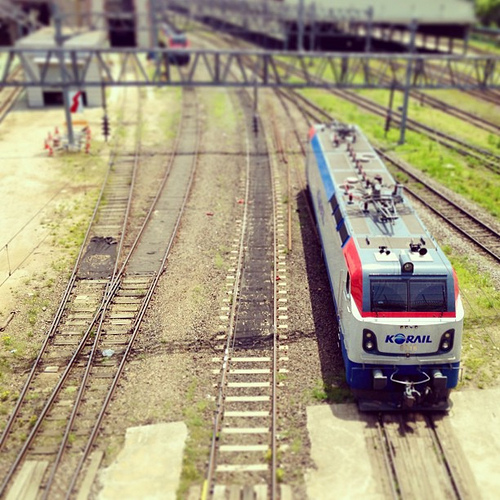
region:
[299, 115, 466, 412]
the train on the railroad tracks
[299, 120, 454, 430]
the model toy train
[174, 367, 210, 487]
the grass on the ground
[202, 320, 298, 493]
the railroad tracks on the ground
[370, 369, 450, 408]
the front bumper of the train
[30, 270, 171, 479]
the splits in the train tracks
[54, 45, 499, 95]
the scaffolding above the train tracks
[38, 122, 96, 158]
the orange cones on the ground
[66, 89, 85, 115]
the white electrical sign on the pole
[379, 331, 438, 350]
BRAND NAME OF TRAIN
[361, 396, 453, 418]
FRONT BUMPER OF TRAIN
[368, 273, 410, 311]
FRONT WINDSHIELD OF TRAIN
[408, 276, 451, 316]
FRONT WINDSHIELD OF TRAIN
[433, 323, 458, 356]
HEADLIGHT OF MOVING TRAIN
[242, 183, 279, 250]
PART OF TRACKS NEAR TRAIN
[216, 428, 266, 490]
PART OF TRACKS NEA TRAIN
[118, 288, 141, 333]
PART OF TRACKS NEAR TRAIN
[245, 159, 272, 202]
PART OF TRACKS NEAR TRAIN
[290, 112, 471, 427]
train on the tracks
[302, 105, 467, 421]
red, white, and blue train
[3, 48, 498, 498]
several sets of train tracks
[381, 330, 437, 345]
blue writing on the front of the train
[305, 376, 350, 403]
patch of grass in the gravel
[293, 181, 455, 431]
shadow from the train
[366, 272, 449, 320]
windows on the front of the train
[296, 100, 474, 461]
train has only one car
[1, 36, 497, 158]
silver structure over the train tracks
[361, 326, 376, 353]
lights on the front of the train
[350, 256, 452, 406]
the front of a korail train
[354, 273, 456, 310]
the window of a korail train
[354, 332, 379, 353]
the lights of a korail train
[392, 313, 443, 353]
the logo of a korail train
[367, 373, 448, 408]
the metal link of a korail train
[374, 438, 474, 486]
the rail of a korail train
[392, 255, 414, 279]
the top light of a korail train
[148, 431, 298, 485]
a bunch of wooden rails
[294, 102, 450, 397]
train on the tracos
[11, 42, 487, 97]
metal rail going over the tracks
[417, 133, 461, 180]
weeds growing between the tracks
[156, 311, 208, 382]
gravel between the tracks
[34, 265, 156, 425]
two tracks crossing each other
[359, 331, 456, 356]
lights on the front of the train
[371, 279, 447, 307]
windshield on front of the train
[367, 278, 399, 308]
reflection in the windshield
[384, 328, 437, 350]
logo on front of trin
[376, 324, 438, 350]
logo is blue in color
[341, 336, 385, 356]
headlight on front of train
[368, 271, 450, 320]
windshield on front of train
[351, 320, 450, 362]
front of train is white in color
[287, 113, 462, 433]
train is white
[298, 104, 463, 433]
train is on the tracks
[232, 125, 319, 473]
tracks have a train on it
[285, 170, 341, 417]
gravel on the side of the tracks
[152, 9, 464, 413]
Two trains on railroad tracks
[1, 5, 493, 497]
Rail road tracks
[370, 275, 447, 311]
Front window of closest train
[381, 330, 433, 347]
Brand name of train company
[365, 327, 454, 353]
headlights on front of train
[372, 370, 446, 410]
Hook for attaching to other train cars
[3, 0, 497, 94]
Metal railing over train tracks